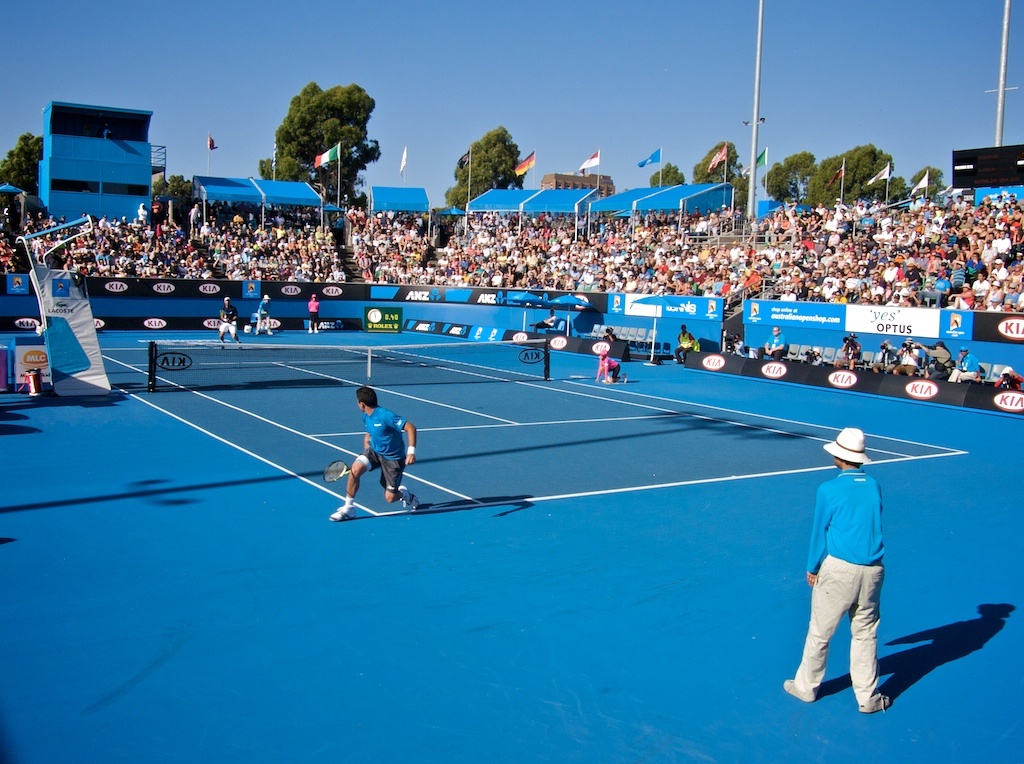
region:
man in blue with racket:
[312, 357, 439, 542]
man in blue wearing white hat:
[773, 356, 907, 740]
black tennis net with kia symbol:
[130, 315, 567, 418]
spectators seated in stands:
[31, 152, 1009, 362]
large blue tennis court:
[41, 309, 1012, 762]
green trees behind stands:
[285, 78, 938, 211]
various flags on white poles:
[209, 129, 981, 193]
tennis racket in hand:
[318, 445, 372, 496]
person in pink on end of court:
[297, 281, 326, 346]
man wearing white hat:
[770, 414, 913, 713]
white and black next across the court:
[139, 341, 552, 395]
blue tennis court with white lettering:
[64, 313, 982, 538]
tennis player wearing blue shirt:
[306, 368, 437, 521]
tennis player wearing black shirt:
[217, 292, 252, 344]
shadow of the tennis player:
[414, 474, 542, 522]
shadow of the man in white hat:
[816, 573, 1022, 701]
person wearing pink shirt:
[590, 346, 626, 388]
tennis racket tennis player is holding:
[309, 449, 354, 492]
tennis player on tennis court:
[337, 391, 446, 516]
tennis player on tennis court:
[203, 297, 232, 345]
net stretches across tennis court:
[137, 329, 606, 380]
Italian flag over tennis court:
[301, 133, 337, 163]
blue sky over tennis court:
[35, 6, 1015, 191]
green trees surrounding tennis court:
[156, 64, 918, 214]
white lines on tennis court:
[620, 464, 737, 515]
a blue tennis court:
[134, 329, 827, 602]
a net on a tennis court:
[144, 327, 559, 404]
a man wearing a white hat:
[826, 427, 887, 472]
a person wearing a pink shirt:
[596, 348, 620, 378]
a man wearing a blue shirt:
[816, 471, 883, 555]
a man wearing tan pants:
[819, 554, 881, 713]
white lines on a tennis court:
[204, 371, 316, 477]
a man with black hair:
[358, 386, 382, 409]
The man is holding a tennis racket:
[289, 300, 483, 570]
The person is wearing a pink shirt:
[577, 326, 651, 459]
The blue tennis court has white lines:
[61, 268, 927, 645]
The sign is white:
[830, 268, 985, 374]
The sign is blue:
[724, 275, 851, 362]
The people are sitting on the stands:
[725, 154, 921, 335]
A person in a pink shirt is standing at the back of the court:
[229, 249, 388, 402]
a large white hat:
[816, 427, 886, 466]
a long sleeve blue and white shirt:
[810, 467, 888, 573]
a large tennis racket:
[323, 458, 356, 482]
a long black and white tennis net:
[146, 332, 562, 384]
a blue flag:
[627, 149, 666, 169]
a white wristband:
[400, 440, 417, 454]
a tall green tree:
[257, 78, 393, 202]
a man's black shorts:
[359, 445, 404, 494]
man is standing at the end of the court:
[782, 425, 890, 711]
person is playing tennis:
[324, 384, 416, 520]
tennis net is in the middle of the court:
[146, 337, 552, 391]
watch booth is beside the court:
[11, 213, 107, 392]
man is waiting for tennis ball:
[213, 292, 240, 347]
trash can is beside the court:
[23, 365, 43, 394]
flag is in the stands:
[513, 150, 537, 186]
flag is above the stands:
[579, 141, 600, 189]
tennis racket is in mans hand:
[324, 454, 347, 480]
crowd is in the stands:
[0, 183, 1023, 321]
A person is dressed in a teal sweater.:
[773, 405, 923, 729]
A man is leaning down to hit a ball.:
[313, 373, 431, 539]